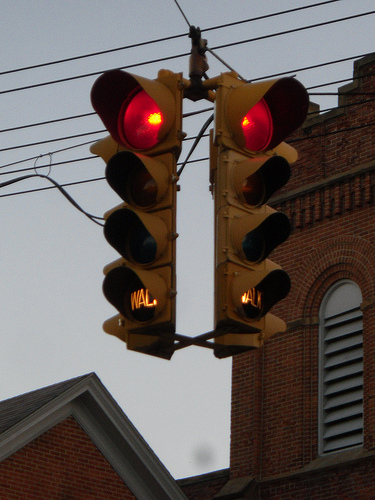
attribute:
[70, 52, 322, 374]
traffic lights — set, orange, yellow, red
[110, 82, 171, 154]
light — red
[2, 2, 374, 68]
wires — light-gray, black, gray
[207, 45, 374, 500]
building — brick, red, tall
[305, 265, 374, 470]
arched windows — white, shutter-style, large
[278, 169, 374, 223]
bricks — short, forming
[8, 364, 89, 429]
roof — grey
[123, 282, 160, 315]
yellow words — walk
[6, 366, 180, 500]
building — high white, gable